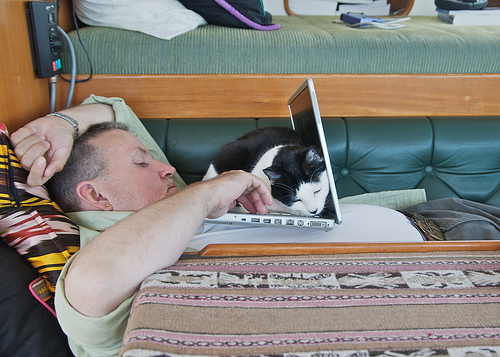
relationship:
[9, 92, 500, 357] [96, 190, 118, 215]
guy wears earring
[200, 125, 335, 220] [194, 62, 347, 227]
cat laying on laptop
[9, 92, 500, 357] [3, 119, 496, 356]
guy on couch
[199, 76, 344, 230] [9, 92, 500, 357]
laptop on guy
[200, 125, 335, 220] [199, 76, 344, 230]
cat on laptop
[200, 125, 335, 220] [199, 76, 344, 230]
cat laying on laptop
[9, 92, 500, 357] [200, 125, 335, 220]
guy working around cat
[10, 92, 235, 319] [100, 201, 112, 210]
dude wearing an earring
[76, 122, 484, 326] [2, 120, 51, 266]
guy leaning against pillow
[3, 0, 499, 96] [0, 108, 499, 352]
bed above sofa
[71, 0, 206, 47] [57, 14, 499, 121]
pillow on upper bed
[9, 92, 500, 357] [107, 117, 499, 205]
guy on couch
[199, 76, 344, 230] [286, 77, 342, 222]
laptop has screen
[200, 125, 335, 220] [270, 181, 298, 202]
cat has whiskers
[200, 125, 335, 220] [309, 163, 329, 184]
cat has whiskers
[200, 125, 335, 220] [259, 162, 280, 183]
cat has ear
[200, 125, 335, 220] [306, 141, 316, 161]
cat has ear